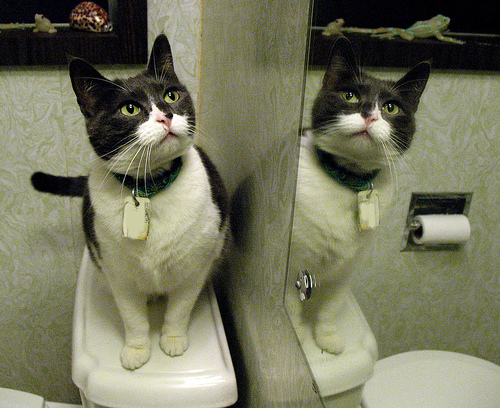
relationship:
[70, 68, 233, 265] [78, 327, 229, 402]
cat on toilet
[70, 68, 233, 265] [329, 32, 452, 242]
cat in mirror